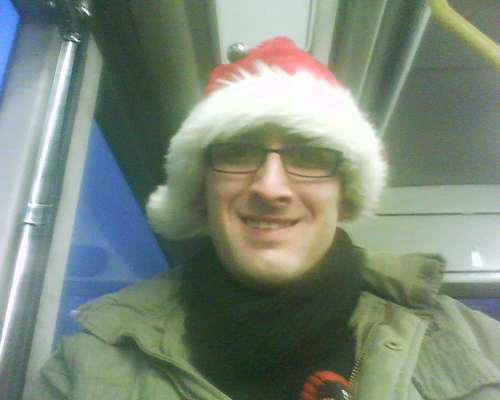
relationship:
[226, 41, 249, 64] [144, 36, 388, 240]
bell on santa hat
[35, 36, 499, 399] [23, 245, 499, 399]
man wearing coat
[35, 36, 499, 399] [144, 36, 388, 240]
man wearing santa hat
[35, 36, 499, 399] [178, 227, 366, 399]
man wearing scarf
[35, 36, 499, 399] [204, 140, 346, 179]
man wearing glasses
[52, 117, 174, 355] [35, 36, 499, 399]
window behind man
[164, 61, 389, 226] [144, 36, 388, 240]
brim on santa hat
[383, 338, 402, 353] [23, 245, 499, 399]
button on coat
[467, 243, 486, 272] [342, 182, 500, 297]
reflection on wall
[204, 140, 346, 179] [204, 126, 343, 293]
glasses on face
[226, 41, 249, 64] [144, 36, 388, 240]
bell on top of santa hat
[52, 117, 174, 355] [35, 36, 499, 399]
window next to man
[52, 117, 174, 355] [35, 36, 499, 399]
window beside man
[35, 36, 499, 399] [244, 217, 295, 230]
man has teeth